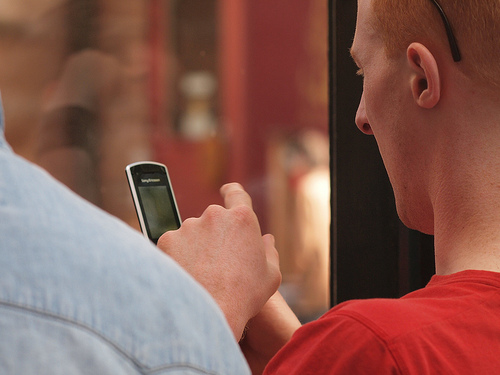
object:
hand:
[157, 181, 284, 316]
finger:
[219, 181, 250, 207]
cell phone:
[124, 160, 182, 246]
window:
[0, 0, 331, 375]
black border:
[326, 0, 438, 306]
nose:
[353, 90, 371, 137]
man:
[155, 0, 499, 374]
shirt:
[254, 270, 499, 375]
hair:
[368, 0, 500, 92]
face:
[350, 0, 433, 234]